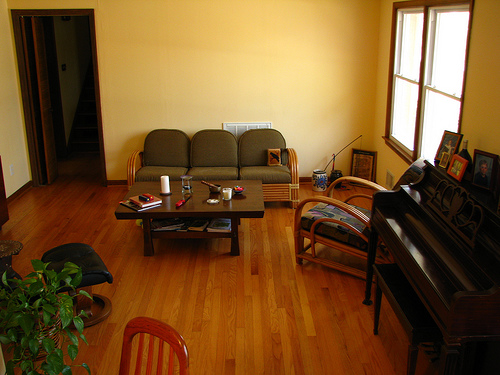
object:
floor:
[4, 174, 443, 372]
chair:
[119, 314, 192, 373]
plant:
[3, 255, 93, 372]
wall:
[375, 2, 495, 192]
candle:
[159, 175, 170, 194]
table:
[114, 178, 264, 216]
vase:
[309, 169, 329, 192]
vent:
[221, 119, 274, 139]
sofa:
[122, 123, 302, 206]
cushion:
[299, 190, 371, 250]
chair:
[283, 156, 425, 289]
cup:
[222, 187, 233, 201]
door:
[9, 3, 112, 190]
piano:
[358, 151, 500, 375]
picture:
[470, 148, 499, 190]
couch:
[119, 124, 302, 214]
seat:
[39, 241, 115, 330]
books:
[118, 192, 163, 213]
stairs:
[58, 15, 108, 183]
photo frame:
[446, 153, 470, 183]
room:
[1, 1, 499, 368]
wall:
[3, 3, 378, 183]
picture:
[348, 147, 377, 190]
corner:
[311, 1, 389, 196]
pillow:
[266, 147, 282, 167]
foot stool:
[24, 241, 113, 331]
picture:
[446, 154, 469, 182]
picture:
[433, 130, 464, 168]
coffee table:
[108, 179, 268, 257]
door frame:
[5, 1, 113, 184]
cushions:
[138, 125, 188, 176]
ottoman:
[36, 241, 117, 330]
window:
[381, 10, 471, 178]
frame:
[376, 3, 474, 173]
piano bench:
[360, 257, 455, 373]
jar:
[312, 168, 329, 192]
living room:
[0, 3, 498, 368]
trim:
[120, 149, 301, 206]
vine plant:
[0, 257, 91, 373]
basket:
[11, 308, 63, 370]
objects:
[158, 174, 172, 195]